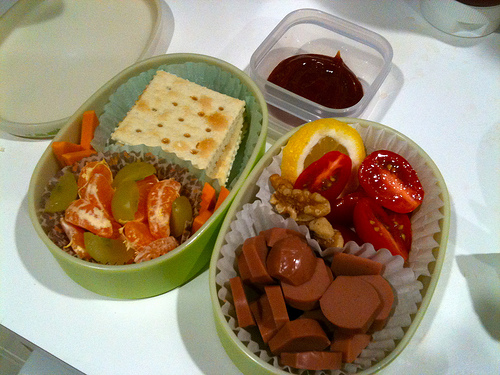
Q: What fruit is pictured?
A: Tomatoes, oranges, grapes and lemons.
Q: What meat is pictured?
A: Sliced hot dogs.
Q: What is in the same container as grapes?
A: Saltines.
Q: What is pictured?
A: Someone's lunch.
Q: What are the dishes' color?
A: Green.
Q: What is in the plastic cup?
A: Dipping sauce.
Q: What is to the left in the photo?
A: The lid to the dish.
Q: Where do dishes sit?
A: White table.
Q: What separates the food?
A: Tissue paper.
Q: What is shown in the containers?
A: Food.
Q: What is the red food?
A: Tomatoes.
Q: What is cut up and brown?
A: Hot dog.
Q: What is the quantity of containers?
A: Two.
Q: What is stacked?
A: Saltine crackers.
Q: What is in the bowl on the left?
A: Orange sections.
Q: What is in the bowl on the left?
A: Green grapes.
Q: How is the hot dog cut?
A: Bite sized pieces.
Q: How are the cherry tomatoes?
A: Cut up.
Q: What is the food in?
A: Two white cupcake baking cups.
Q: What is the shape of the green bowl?
A: Oval.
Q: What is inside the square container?
A: Sauce.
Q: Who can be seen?
A: No one.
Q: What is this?
A: A lunch.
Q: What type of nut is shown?
A: Walnuts.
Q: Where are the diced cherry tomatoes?
A: In the right container.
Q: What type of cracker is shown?
A: Saltines.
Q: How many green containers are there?
A: Two.